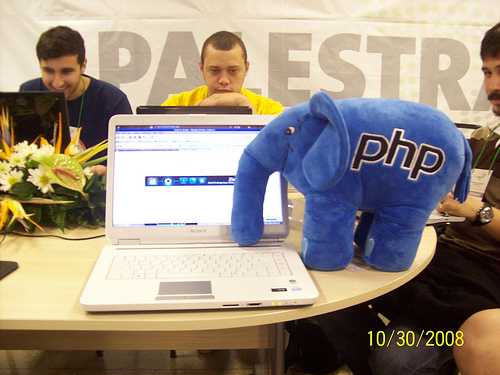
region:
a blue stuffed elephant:
[151, 52, 471, 316]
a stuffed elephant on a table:
[175, 97, 470, 302]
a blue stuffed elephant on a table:
[172, 39, 465, 264]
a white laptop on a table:
[73, 77, 370, 331]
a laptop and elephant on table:
[82, 88, 464, 334]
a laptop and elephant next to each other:
[80, 64, 463, 332]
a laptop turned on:
[59, 72, 333, 327]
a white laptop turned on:
[86, 87, 363, 324]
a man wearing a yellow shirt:
[141, 21, 338, 146]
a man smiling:
[12, 7, 149, 153]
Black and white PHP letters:
[356, 128, 447, 183]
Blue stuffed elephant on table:
[233, 98, 471, 262]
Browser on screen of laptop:
[118, 125, 282, 226]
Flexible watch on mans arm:
[473, 204, 496, 226]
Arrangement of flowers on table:
[2, 134, 94, 225]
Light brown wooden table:
[17, 238, 73, 323]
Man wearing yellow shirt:
[168, 36, 279, 113]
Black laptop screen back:
[1, 91, 69, 136]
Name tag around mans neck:
[471, 166, 491, 195]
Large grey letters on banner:
[320, 31, 468, 106]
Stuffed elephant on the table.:
[235, 48, 466, 214]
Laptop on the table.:
[63, 98, 348, 315]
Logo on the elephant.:
[358, 124, 458, 179]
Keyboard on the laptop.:
[90, 233, 396, 330]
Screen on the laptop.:
[103, 99, 282, 229]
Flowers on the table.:
[2, 115, 129, 256]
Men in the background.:
[28, 20, 307, 135]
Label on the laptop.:
[263, 272, 319, 303]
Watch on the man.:
[450, 175, 493, 263]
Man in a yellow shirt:
[144, 34, 432, 236]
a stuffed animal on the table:
[222, 89, 475, 273]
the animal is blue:
[231, 90, 462, 267]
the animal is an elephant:
[205, 92, 472, 277]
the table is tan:
[1, 222, 71, 322]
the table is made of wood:
[10, 257, 87, 328]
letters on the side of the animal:
[343, 118, 450, 195]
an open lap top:
[78, 102, 323, 306]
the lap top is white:
[81, 93, 327, 325]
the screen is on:
[113, 128, 278, 230]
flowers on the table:
[1, 125, 102, 237]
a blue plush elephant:
[232, 88, 474, 272]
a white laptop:
[75, 113, 318, 313]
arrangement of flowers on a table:
[0, 113, 106, 239]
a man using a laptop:
[138, 31, 282, 123]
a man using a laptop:
[0, 27, 131, 156]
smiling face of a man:
[38, 28, 86, 97]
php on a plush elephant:
[352, 122, 447, 185]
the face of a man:
[481, 23, 498, 117]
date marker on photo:
[366, 329, 463, 348]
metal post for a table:
[271, 326, 287, 374]